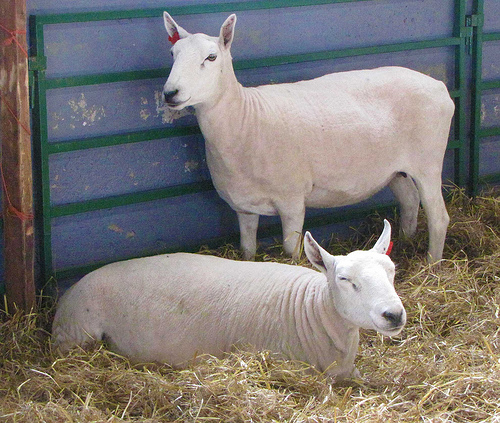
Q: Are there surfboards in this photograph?
A: No, there are no surfboards.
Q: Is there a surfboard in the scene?
A: No, there are no surfboards.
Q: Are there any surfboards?
A: No, there are no surfboards.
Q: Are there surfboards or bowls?
A: No, there are no surfboards or bowls.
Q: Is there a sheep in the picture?
A: Yes, there is a sheep.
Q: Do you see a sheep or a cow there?
A: Yes, there is a sheep.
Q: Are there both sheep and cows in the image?
A: No, there is a sheep but no cows.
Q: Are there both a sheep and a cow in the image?
A: No, there is a sheep but no cows.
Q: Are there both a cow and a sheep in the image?
A: No, there is a sheep but no cows.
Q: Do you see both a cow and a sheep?
A: No, there is a sheep but no cows.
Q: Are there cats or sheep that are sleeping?
A: Yes, the sheep is sleeping.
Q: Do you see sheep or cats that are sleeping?
A: Yes, the sheep is sleeping.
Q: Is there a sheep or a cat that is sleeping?
A: Yes, the sheep is sleeping.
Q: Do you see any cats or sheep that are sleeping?
A: Yes, the sheep is sleeping.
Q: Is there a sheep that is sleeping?
A: Yes, there is a sheep that is sleeping.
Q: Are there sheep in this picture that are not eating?
A: Yes, there is a sheep that is sleeping.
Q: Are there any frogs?
A: No, there are no frogs.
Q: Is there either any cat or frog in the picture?
A: No, there are no frogs or cats.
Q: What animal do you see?
A: The animal is a sheep.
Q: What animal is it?
A: The animal is a sheep.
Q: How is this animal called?
A: This is a sheep.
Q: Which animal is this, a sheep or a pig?
A: This is a sheep.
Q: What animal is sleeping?
A: The animal is a sheep.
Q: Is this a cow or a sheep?
A: This is a sheep.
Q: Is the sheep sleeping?
A: Yes, the sheep is sleeping.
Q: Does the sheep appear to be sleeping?
A: Yes, the sheep is sleeping.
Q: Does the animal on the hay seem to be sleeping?
A: Yes, the sheep is sleeping.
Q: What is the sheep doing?
A: The sheep is sleeping.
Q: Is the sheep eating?
A: No, the sheep is sleeping.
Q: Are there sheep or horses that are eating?
A: No, there is a sheep but it is sleeping.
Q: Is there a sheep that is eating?
A: No, there is a sheep but it is sleeping.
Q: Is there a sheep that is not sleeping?
A: No, there is a sheep but it is sleeping.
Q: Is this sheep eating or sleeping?
A: The sheep is sleeping.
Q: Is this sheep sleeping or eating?
A: The sheep is sleeping.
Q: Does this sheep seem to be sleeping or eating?
A: The sheep is sleeping.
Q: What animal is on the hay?
A: The sheep is on the hay.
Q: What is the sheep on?
A: The sheep is on the hay.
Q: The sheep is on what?
A: The sheep is on the hay.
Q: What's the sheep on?
A: The sheep is on the hay.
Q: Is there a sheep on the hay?
A: Yes, there is a sheep on the hay.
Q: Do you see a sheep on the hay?
A: Yes, there is a sheep on the hay.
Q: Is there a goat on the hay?
A: No, there is a sheep on the hay.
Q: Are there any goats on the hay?
A: No, there is a sheep on the hay.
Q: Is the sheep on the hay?
A: Yes, the sheep is on the hay.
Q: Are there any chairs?
A: No, there are no chairs.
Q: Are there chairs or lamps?
A: No, there are no chairs or lamps.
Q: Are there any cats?
A: No, there are no cats.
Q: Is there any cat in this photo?
A: No, there are no cats.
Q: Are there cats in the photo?
A: No, there are no cats.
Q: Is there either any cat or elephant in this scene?
A: No, there are no cats or elephants.